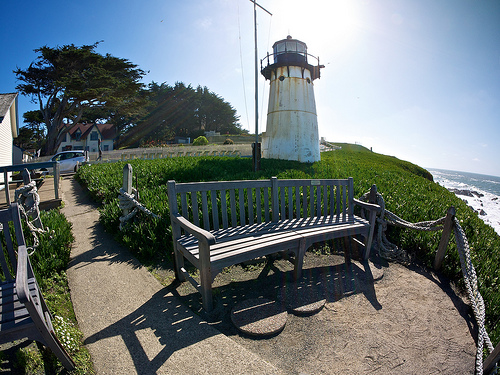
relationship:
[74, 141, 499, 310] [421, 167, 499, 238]
ground by ocean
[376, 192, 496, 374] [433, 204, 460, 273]
rope on post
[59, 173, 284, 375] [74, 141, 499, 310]
sidewalk on ground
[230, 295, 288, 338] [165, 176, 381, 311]
step below bench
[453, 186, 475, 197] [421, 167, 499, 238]
rock in ocean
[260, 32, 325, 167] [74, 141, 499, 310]
lighthouse on ground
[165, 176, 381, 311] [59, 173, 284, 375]
bench by sidewalk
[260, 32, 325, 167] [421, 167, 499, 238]
lighthouse by ocean